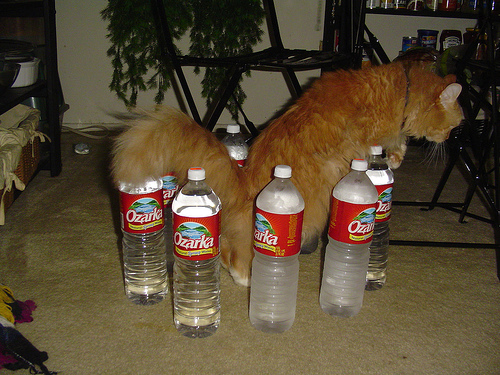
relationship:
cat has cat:
[109, 61, 466, 286] [109, 61, 466, 286]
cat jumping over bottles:
[109, 61, 466, 286] [366, 138, 392, 288]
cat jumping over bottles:
[109, 61, 466, 286] [246, 162, 306, 333]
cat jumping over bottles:
[109, 61, 466, 286] [318, 159, 381, 320]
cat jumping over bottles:
[109, 61, 466, 286] [166, 164, 223, 339]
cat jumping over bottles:
[109, 61, 466, 286] [116, 158, 171, 301]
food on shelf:
[399, 35, 421, 61] [321, 7, 498, 77]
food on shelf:
[395, 31, 422, 54] [321, 7, 498, 77]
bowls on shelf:
[0, 25, 49, 118] [3, 40, 75, 132]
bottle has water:
[245, 158, 305, 331] [318, 158, 378, 318]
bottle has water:
[319, 153, 372, 318] [247, 160, 302, 332]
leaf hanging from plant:
[152, 44, 165, 56] [99, 4, 268, 115]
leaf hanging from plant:
[116, 89, 127, 102] [99, 4, 268, 115]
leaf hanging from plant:
[109, 75, 121, 91] [99, 4, 268, 115]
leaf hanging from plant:
[143, 76, 156, 87] [99, 4, 268, 115]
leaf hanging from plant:
[134, 5, 147, 24] [99, 4, 268, 115]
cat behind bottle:
[109, 61, 466, 286] [172, 168, 222, 332]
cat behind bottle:
[109, 61, 466, 286] [367, 146, 394, 292]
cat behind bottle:
[109, 61, 466, 286] [319, 159, 378, 317]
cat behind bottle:
[109, 61, 466, 286] [116, 181, 170, 304]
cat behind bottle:
[109, 61, 466, 286] [249, 164, 306, 332]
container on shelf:
[415, 26, 440, 51] [323, 5, 496, 70]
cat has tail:
[104, 56, 465, 264] [114, 120, 246, 217]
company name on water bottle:
[173, 230, 215, 251] [171, 165, 221, 337]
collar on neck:
[401, 59, 413, 126] [394, 62, 424, 134]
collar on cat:
[401, 59, 413, 126] [109, 61, 466, 286]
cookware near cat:
[17, 44, 75, 128] [177, 59, 468, 206]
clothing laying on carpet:
[1, 284, 56, 370] [1, 127, 499, 373]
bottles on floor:
[104, 99, 401, 327] [123, 326, 301, 373]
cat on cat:
[109, 61, 466, 286] [109, 61, 466, 286]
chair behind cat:
[146, 0, 357, 132] [109, 61, 466, 286]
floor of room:
[123, 326, 301, 373] [2, 5, 498, 373]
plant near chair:
[87, 0, 268, 161] [146, 2, 347, 153]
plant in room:
[87, 0, 268, 161] [2, 5, 498, 373]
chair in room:
[146, 2, 347, 153] [2, 5, 498, 373]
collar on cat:
[398, 59, 413, 132] [109, 61, 466, 286]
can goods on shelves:
[366, 0, 498, 67] [326, 0, 498, 74]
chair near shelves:
[146, 0, 357, 132] [326, 0, 498, 74]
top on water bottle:
[272, 164, 294, 179] [249, 162, 308, 331]